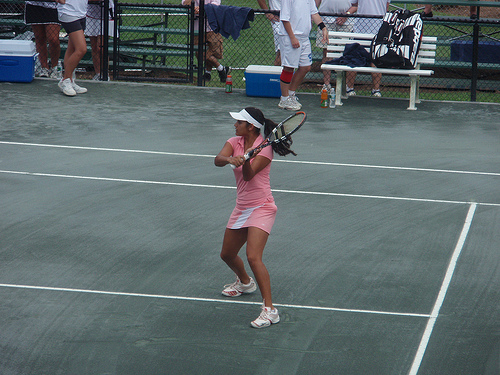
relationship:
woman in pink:
[233, 92, 286, 295] [253, 197, 283, 240]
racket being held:
[270, 112, 318, 151] [242, 150, 261, 177]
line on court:
[423, 204, 461, 374] [96, 160, 184, 283]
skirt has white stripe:
[228, 209, 261, 238] [238, 203, 251, 232]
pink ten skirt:
[253, 197, 283, 240] [228, 209, 261, 238]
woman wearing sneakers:
[233, 92, 286, 295] [247, 306, 297, 328]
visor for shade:
[223, 108, 264, 126] [226, 110, 241, 123]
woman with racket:
[233, 92, 286, 295] [270, 112, 318, 151]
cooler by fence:
[6, 42, 50, 90] [212, 15, 240, 87]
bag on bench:
[384, 14, 425, 75] [333, 23, 437, 107]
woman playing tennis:
[213, 104, 276, 327] [138, 95, 442, 340]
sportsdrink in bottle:
[224, 70, 237, 98] [224, 84, 232, 91]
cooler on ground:
[240, 62, 290, 103] [236, 86, 296, 106]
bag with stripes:
[384, 14, 425, 75] [400, 20, 424, 61]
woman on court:
[233, 92, 286, 295] [96, 160, 184, 283]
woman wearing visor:
[233, 92, 286, 295] [223, 108, 264, 126]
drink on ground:
[320, 82, 328, 111] [315, 110, 339, 118]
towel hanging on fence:
[206, 5, 254, 37] [212, 15, 240, 87]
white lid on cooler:
[2, 40, 37, 54] [6, 42, 50, 90]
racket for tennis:
[270, 112, 318, 151] [138, 95, 442, 340]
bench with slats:
[333, 23, 437, 107] [331, 29, 349, 60]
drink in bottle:
[320, 82, 328, 111] [224, 84, 232, 91]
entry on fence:
[102, 9, 217, 89] [212, 15, 240, 87]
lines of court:
[21, 125, 156, 203] [96, 160, 184, 283]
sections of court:
[22, 199, 198, 335] [96, 160, 184, 283]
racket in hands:
[270, 112, 318, 151] [232, 154, 246, 171]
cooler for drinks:
[6, 42, 50, 90] [317, 81, 348, 125]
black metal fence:
[450, 22, 499, 97] [212, 15, 240, 87]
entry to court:
[102, 46, 217, 110] [96, 160, 184, 283]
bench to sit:
[333, 23, 437, 107] [359, 34, 391, 85]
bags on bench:
[336, 33, 425, 90] [333, 23, 437, 107]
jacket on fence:
[201, 5, 264, 46] [212, 15, 240, 87]